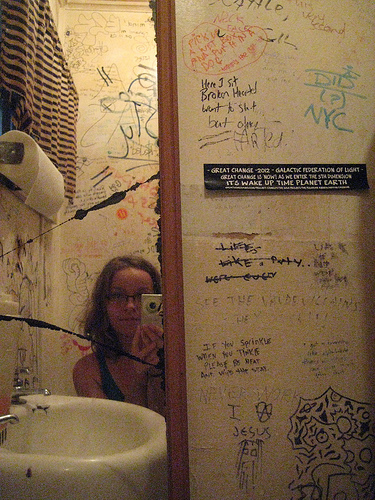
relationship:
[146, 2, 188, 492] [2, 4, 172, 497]
wood frame of mirror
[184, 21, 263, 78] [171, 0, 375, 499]
red ink on wall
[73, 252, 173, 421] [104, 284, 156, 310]
girl wearing glasses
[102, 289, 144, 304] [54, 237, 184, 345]
eyeglasses on face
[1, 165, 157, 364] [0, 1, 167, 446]
cracks in mirror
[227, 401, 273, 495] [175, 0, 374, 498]
writing on wall